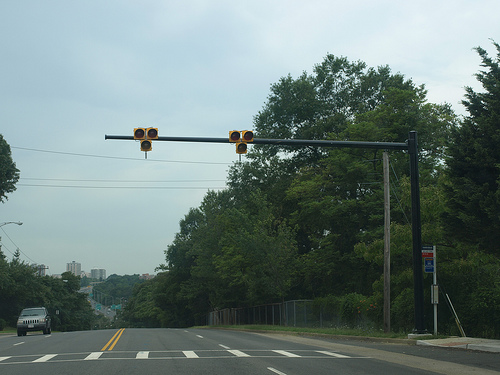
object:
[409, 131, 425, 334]
steel pole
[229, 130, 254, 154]
traffic light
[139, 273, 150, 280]
buildings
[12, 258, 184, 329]
distance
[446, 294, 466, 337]
metal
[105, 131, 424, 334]
lightpole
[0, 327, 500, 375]
street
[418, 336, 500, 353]
sidewalk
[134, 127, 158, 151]
light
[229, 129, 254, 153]
light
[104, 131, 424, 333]
pole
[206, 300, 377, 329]
fencing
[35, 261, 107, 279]
buildings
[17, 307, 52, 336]
car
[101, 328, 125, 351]
line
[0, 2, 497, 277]
sky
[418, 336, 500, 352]
concrete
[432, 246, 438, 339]
post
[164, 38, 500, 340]
green tree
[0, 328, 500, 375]
road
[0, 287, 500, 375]
long road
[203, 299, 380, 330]
fence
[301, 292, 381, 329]
plant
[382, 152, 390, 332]
pole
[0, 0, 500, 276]
overcast skies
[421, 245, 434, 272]
sign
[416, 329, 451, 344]
base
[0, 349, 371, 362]
crossing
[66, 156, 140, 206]
clouds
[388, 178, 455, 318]
cords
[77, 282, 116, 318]
street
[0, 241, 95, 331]
trees